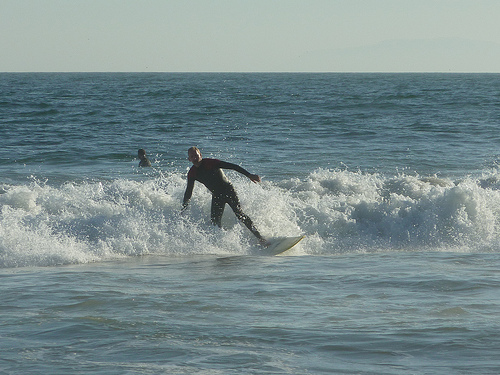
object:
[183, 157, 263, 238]
wetsuit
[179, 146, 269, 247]
man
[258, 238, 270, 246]
foot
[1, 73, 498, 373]
water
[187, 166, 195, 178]
shoulders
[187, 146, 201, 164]
head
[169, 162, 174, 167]
water drop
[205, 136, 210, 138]
water drop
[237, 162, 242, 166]
water drop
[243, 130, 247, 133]
water drop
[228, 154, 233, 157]
water drop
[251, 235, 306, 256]
surfboard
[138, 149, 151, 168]
person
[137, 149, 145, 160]
head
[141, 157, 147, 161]
shoulders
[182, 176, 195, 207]
arm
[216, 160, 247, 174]
arm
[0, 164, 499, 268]
waves